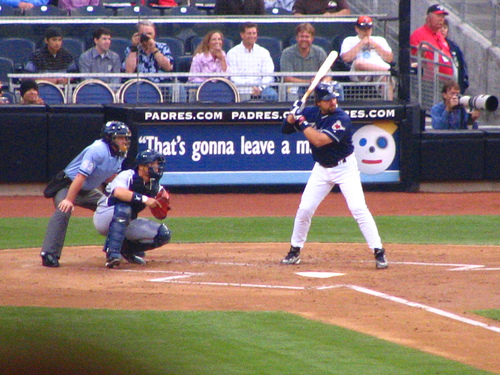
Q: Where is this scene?
A: A ballpark.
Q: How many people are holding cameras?
A: Two.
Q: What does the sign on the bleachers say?
A: That's gonna leave a mark.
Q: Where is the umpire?
A: Behind the catcher.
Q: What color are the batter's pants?
A: White.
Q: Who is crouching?
A: The catcher.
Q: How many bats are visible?
A: One.